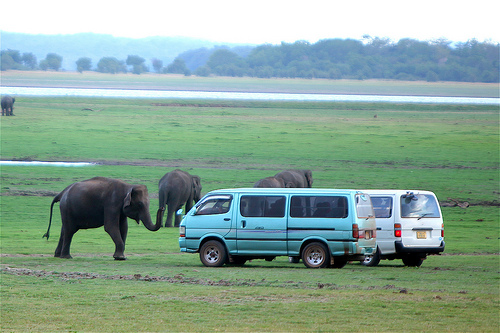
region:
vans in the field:
[175, 185, 448, 260]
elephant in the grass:
[53, 174, 170, 259]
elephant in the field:
[147, 156, 187, 228]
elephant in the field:
[253, 163, 313, 185]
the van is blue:
[244, 241, 269, 251]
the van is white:
[410, 220, 435, 228]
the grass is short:
[272, 304, 336, 329]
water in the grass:
[0, 155, 87, 172]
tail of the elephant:
[37, 198, 56, 234]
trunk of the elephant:
[148, 203, 169, 240]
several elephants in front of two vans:
[31, 144, 468, 306]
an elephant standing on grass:
[33, 170, 167, 280]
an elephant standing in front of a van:
[35, 170, 386, 285]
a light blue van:
[168, 179, 380, 277]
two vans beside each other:
[176, 178, 448, 283]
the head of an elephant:
[124, 175, 169, 239]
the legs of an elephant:
[51, 223, 131, 270]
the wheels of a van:
[196, 238, 332, 276]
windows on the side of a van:
[243, 196, 347, 218]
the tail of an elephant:
[26, 193, 60, 245]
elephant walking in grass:
[40, 173, 162, 261]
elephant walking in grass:
[157, 168, 203, 226]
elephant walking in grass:
[254, 174, 289, 208]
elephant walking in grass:
[286, 163, 312, 190]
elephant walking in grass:
[0, 95, 18, 116]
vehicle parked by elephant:
[176, 185, 373, 267]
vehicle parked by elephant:
[361, 187, 443, 266]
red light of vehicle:
[355, 226, 360, 239]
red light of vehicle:
[394, 224, 406, 239]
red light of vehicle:
[440, 226, 447, 241]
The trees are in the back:
[173, 45, 398, 124]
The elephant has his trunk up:
[17, 145, 175, 264]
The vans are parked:
[170, 188, 482, 276]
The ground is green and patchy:
[90, 251, 190, 330]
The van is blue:
[189, 205, 341, 262]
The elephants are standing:
[30, 130, 345, 280]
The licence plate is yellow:
[410, 225, 433, 242]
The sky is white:
[154, 11, 221, 33]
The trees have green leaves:
[110, 31, 242, 117]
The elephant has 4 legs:
[45, 221, 156, 275]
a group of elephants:
[36, 148, 193, 268]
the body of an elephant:
[40, 168, 167, 270]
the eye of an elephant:
[130, 195, 143, 210]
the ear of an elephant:
[115, 185, 134, 212]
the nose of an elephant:
[130, 199, 169, 233]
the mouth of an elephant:
[128, 212, 145, 227]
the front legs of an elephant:
[97, 216, 122, 263]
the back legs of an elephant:
[45, 220, 80, 261]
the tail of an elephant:
[40, 185, 74, 266]